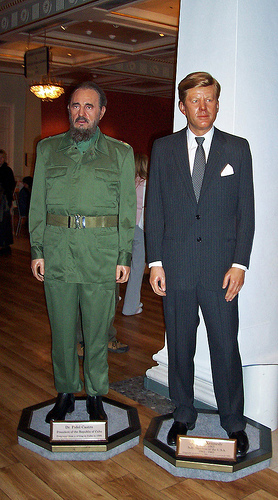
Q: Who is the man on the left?
A: Fidel Castro.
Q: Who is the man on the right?
A: John F. Kennedy.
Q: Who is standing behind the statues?
A: A woman.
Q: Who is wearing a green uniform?
A: Fidel Castro.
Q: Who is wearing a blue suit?
A: John F. Kennedy.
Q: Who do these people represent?
A: Countries.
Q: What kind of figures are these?
A: Wax.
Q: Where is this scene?
A: A musuem.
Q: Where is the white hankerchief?
A: In the suit pocket.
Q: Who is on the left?
A: Fidel Castro.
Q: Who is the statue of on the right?
A: John F Kennedy.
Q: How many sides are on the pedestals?
A: 8.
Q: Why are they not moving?
A: They are statues.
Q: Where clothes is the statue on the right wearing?
A: A suit.